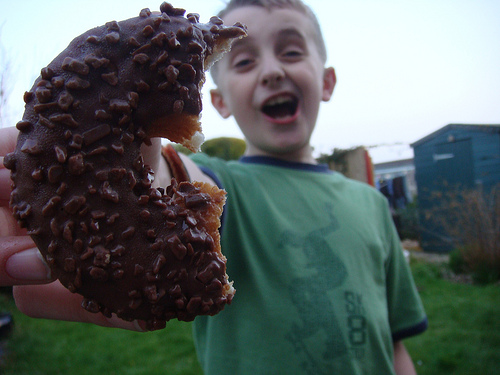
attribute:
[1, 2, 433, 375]
boy — young, showing off, smiling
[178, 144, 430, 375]
shirt — green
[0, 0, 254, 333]
doughnut — chocolate, bitten, being held, half eaten, chocolate covered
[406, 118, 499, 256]
shed — blue gray, blue green, blue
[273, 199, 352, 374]
design — black, green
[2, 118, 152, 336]
fingers — enlarged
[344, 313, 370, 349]
number — black, 8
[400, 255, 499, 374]
grass — undulating, terrain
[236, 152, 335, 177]
collar — blue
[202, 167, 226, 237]
strip — blue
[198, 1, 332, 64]
hair — blonde